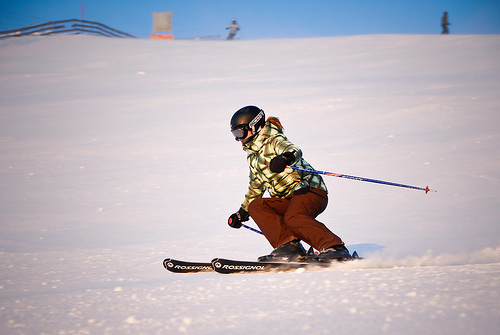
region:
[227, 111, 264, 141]
Goggles on skiers face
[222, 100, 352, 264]
Skier wearing brown pants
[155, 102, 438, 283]
person skiing down hillside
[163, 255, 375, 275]
Skies worn by person in the snow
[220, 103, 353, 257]
Woman wearing a multicolored jacket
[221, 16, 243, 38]
person on the top of hill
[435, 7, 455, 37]
Person on top of hill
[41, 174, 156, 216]
white snow on the ground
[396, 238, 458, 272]
trail of white snow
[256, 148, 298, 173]
black glove on skier's hand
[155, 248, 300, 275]
black ski in snow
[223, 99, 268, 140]
black helmet on head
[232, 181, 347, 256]
red skier's pants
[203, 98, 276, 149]
black goggles on skier's face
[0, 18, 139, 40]
wooden fence on hill top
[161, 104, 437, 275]
person is skiing in snow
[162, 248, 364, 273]
skis are black and white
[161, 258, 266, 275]
white words on skis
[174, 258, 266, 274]
white words on skis say ROSSIGNOL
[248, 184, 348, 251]
brown pants on person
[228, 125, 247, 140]
person is wearing ski goggles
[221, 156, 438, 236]
person is holding ski poles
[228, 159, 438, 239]
ski poles are blue and red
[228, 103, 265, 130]
person has black helmet on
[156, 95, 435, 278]
A man skiing down a slope.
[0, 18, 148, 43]
A wooden plank fence.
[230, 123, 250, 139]
A pair of snow goggles.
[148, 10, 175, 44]
A white sign.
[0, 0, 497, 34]
A blue sky.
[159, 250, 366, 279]
A pair of skis.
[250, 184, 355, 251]
A pair of snow pants.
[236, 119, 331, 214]
A plaid sweatshirt.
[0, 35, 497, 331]
A snow covered mountain.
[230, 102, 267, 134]
A shiny brown helmet.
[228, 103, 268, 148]
a person wearing a helmet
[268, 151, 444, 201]
a person holding a ski pole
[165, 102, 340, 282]
a person skiing in the snow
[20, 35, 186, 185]
the ground covered in snow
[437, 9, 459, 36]
a person walking in the snow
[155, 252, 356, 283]
black skis with white letters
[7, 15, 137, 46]
a fence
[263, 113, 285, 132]
a person's hair hanging out of a helmet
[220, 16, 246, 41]
a person skiing down a hill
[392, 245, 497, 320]
tracks in the snow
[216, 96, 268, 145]
the helmet is black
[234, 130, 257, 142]
the goggles are black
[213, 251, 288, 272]
the ski is black